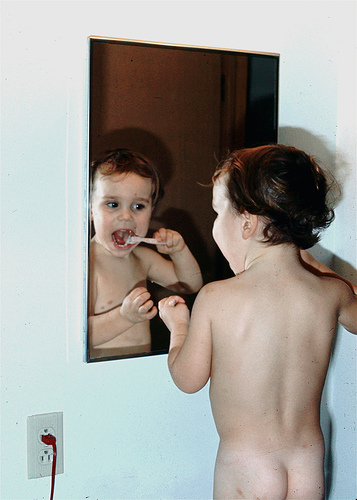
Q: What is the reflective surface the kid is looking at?
A: Mirror.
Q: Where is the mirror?
A: On the wall.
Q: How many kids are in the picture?
A: One.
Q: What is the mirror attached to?
A: The wall.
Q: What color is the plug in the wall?
A: Red.